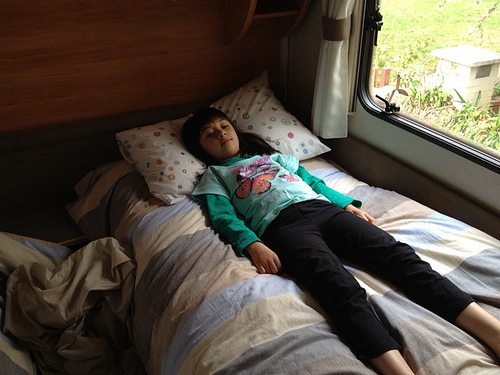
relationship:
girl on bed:
[180, 106, 498, 375] [62, 141, 499, 374]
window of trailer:
[340, 0, 498, 179] [2, 2, 500, 375]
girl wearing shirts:
[180, 106, 498, 375] [193, 147, 365, 258]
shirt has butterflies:
[196, 150, 340, 241] [228, 155, 308, 202]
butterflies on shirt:
[228, 155, 308, 202] [196, 150, 340, 241]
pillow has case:
[105, 68, 337, 209] [103, 68, 333, 213]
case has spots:
[103, 68, 333, 213] [119, 103, 322, 181]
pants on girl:
[256, 189, 483, 370] [177, 101, 499, 373]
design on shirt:
[205, 148, 305, 213] [196, 150, 340, 241]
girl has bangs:
[177, 101, 499, 373] [189, 104, 237, 130]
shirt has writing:
[196, 150, 340, 241] [226, 155, 276, 177]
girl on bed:
[177, 101, 499, 373] [62, 141, 499, 374]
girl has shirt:
[177, 101, 499, 373] [196, 150, 340, 241]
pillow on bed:
[105, 68, 337, 209] [62, 141, 499, 374]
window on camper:
[340, 0, 498, 179] [4, 4, 499, 373]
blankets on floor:
[0, 199, 179, 374] [5, 187, 249, 374]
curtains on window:
[306, 0, 369, 150] [340, 0, 498, 179]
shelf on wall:
[220, 2, 316, 52] [0, 6, 316, 254]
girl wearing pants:
[177, 101, 499, 373] [256, 189, 483, 370]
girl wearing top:
[177, 101, 499, 373] [193, 147, 365, 258]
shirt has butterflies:
[200, 150, 364, 255] [228, 155, 308, 202]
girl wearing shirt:
[177, 101, 499, 373] [200, 150, 364, 255]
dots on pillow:
[137, 140, 186, 183] [105, 68, 337, 209]